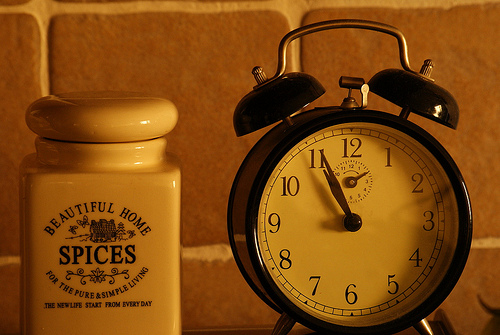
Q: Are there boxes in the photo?
A: No, there are no boxes.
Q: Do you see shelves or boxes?
A: No, there are no boxes or shelves.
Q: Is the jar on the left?
A: Yes, the jar is on the left of the image.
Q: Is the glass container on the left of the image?
A: Yes, the jar is on the left of the image.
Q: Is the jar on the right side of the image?
A: No, the jar is on the left of the image.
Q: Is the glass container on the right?
A: No, the jar is on the left of the image.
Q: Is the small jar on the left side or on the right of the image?
A: The jar is on the left of the image.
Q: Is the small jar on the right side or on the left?
A: The jar is on the left of the image.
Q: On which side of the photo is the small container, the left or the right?
A: The jar is on the left of the image.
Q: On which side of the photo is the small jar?
A: The jar is on the left of the image.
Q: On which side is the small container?
A: The jar is on the left of the image.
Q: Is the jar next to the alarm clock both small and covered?
A: Yes, the jar is small and covered.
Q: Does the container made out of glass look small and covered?
A: Yes, the jar is small and covered.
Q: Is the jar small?
A: Yes, the jar is small.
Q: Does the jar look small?
A: Yes, the jar is small.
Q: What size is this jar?
A: The jar is small.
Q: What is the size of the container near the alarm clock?
A: The jar is small.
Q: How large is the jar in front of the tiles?
A: The jar is small.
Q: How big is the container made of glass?
A: The jar is small.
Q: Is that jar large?
A: No, the jar is small.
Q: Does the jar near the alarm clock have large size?
A: No, the jar is small.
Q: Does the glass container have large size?
A: No, the jar is small.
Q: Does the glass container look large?
A: No, the jar is small.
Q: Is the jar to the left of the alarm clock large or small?
A: The jar is small.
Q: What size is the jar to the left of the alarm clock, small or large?
A: The jar is small.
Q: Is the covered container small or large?
A: The jar is small.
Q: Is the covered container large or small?
A: The jar is small.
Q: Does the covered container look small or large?
A: The jar is small.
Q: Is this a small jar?
A: Yes, this is a small jar.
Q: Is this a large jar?
A: No, this is a small jar.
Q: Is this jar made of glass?
A: Yes, the jar is made of glass.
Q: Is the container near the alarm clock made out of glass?
A: Yes, the jar is made of glass.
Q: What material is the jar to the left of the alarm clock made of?
A: The jar is made of glass.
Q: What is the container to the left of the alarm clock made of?
A: The jar is made of glass.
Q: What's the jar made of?
A: The jar is made of glass.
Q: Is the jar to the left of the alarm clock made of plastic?
A: No, the jar is made of glass.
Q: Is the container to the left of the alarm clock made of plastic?
A: No, the jar is made of glass.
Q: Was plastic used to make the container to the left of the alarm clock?
A: No, the jar is made of glass.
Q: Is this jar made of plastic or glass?
A: The jar is made of glass.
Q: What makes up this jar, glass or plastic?
A: The jar is made of glass.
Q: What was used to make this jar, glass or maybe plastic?
A: The jar is made of glass.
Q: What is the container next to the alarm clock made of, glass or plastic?
A: The jar is made of glass.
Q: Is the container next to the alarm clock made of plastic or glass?
A: The jar is made of glass.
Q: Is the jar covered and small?
A: Yes, the jar is covered and small.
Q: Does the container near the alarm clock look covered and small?
A: Yes, the jar is covered and small.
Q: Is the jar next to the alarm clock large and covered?
A: No, the jar is covered but small.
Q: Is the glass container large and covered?
A: No, the jar is covered but small.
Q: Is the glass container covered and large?
A: No, the jar is covered but small.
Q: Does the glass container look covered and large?
A: No, the jar is covered but small.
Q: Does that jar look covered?
A: Yes, the jar is covered.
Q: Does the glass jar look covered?
A: Yes, the jar is covered.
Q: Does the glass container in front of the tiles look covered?
A: Yes, the jar is covered.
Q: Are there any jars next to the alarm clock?
A: Yes, there is a jar next to the alarm clock.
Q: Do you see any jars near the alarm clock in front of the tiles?
A: Yes, there is a jar near the alarm clock.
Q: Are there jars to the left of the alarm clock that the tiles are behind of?
A: Yes, there is a jar to the left of the alarm clock.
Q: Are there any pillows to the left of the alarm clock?
A: No, there is a jar to the left of the alarm clock.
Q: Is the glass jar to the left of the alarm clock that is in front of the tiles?
A: Yes, the jar is to the left of the alarm clock.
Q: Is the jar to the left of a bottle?
A: No, the jar is to the left of the alarm clock.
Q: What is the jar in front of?
A: The jar is in front of the tiles.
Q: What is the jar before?
A: The jar is in front of the tiles.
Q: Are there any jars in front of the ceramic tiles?
A: Yes, there is a jar in front of the tiles.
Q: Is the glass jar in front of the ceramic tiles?
A: Yes, the jar is in front of the tiles.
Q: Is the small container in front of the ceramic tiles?
A: Yes, the jar is in front of the tiles.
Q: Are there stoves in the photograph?
A: No, there are no stoves.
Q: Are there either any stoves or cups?
A: No, there are no stoves or cups.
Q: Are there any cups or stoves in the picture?
A: No, there are no stoves or cups.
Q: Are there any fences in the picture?
A: No, there are no fences.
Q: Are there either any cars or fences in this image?
A: No, there are no fences or cars.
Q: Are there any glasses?
A: No, there are no glasses.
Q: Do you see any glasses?
A: No, there are no glasses.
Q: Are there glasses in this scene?
A: No, there are no glasses.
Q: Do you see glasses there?
A: No, there are no glasses.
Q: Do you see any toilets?
A: No, there are no toilets.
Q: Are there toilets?
A: No, there are no toilets.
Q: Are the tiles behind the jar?
A: Yes, the tiles are behind the jar.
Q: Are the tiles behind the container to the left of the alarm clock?
A: Yes, the tiles are behind the jar.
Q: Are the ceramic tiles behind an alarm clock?
A: Yes, the tiles are behind an alarm clock.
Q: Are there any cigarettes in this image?
A: No, there are no cigarettes.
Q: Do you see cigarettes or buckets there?
A: No, there are no cigarettes or buckets.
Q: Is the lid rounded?
A: Yes, the lid is rounded.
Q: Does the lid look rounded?
A: Yes, the lid is rounded.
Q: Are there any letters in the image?
A: Yes, there are letters.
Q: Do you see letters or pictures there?
A: Yes, there are letters.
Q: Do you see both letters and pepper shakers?
A: No, there are letters but no pepper shakers.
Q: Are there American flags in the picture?
A: No, there are no American flags.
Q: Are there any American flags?
A: No, there are no American flags.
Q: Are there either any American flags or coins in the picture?
A: No, there are no American flags or coins.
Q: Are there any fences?
A: No, there are no fences.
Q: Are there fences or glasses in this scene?
A: No, there are no fences or glasses.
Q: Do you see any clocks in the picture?
A: Yes, there is a clock.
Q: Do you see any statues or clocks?
A: Yes, there is a clock.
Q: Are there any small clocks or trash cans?
A: Yes, there is a small clock.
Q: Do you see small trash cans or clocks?
A: Yes, there is a small clock.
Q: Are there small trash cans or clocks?
A: Yes, there is a small clock.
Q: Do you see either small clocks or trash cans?
A: Yes, there is a small clock.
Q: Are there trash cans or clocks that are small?
A: Yes, the clock is small.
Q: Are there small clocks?
A: Yes, there is a small clock.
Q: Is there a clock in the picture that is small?
A: Yes, there is a clock that is small.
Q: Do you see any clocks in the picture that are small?
A: Yes, there is a clock that is small.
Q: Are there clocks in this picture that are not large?
A: Yes, there is a small clock.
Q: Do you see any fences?
A: No, there are no fences.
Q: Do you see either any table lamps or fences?
A: No, there are no fences or table lamps.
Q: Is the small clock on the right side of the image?
A: Yes, the clock is on the right of the image.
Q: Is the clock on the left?
A: No, the clock is on the right of the image.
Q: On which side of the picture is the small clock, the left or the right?
A: The clock is on the right of the image.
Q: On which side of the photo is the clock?
A: The clock is on the right of the image.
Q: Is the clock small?
A: Yes, the clock is small.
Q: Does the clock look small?
A: Yes, the clock is small.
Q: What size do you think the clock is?
A: The clock is small.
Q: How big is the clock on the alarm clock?
A: The clock is small.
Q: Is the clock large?
A: No, the clock is small.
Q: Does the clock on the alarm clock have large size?
A: No, the clock is small.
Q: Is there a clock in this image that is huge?
A: No, there is a clock but it is small.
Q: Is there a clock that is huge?
A: No, there is a clock but it is small.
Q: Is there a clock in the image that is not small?
A: No, there is a clock but it is small.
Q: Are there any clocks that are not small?
A: No, there is a clock but it is small.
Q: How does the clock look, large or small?
A: The clock is small.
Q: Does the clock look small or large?
A: The clock is small.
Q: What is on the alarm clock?
A: The clock is on the alarm clock.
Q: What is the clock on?
A: The clock is on the alarm clock.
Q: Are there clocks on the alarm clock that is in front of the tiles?
A: Yes, there is a clock on the alarm clock.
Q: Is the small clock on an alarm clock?
A: Yes, the clock is on an alarm clock.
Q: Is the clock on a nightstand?
A: No, the clock is on an alarm clock.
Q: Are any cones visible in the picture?
A: No, there are no cones.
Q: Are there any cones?
A: No, there are no cones.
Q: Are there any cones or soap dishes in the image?
A: No, there are no cones or soap dishes.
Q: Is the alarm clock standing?
A: Yes, the alarm clock is standing.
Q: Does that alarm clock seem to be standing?
A: Yes, the alarm clock is standing.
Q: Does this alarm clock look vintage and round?
A: Yes, the alarm clock is vintage and round.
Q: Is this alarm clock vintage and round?
A: Yes, the alarm clock is vintage and round.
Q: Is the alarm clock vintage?
A: Yes, the alarm clock is vintage.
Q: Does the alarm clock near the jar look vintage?
A: Yes, the alarm clock is vintage.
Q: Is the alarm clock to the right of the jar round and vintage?
A: Yes, the alarm clock is round and vintage.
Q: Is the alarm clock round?
A: Yes, the alarm clock is round.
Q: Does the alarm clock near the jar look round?
A: Yes, the alarm clock is round.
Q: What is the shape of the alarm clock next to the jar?
A: The alarm clock is round.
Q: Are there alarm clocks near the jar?
A: Yes, there is an alarm clock near the jar.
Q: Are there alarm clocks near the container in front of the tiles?
A: Yes, there is an alarm clock near the jar.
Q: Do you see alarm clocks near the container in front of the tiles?
A: Yes, there is an alarm clock near the jar.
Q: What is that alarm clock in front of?
A: The alarm clock is in front of the tiles.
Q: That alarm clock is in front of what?
A: The alarm clock is in front of the tiles.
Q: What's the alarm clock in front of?
A: The alarm clock is in front of the tiles.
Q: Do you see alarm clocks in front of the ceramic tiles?
A: Yes, there is an alarm clock in front of the tiles.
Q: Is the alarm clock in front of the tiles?
A: Yes, the alarm clock is in front of the tiles.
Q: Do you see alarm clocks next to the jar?
A: Yes, there is an alarm clock next to the jar.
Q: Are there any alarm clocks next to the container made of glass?
A: Yes, there is an alarm clock next to the jar.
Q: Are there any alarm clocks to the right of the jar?
A: Yes, there is an alarm clock to the right of the jar.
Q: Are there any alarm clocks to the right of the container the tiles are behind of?
A: Yes, there is an alarm clock to the right of the jar.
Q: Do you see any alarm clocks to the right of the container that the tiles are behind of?
A: Yes, there is an alarm clock to the right of the jar.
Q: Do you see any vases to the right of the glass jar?
A: No, there is an alarm clock to the right of the jar.